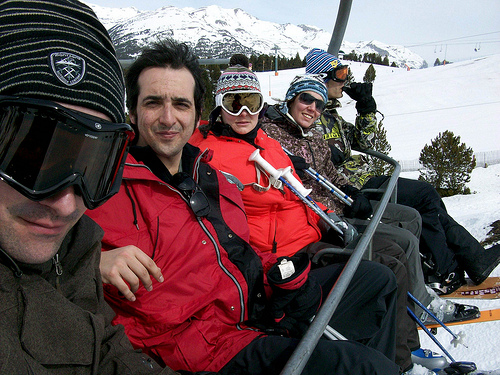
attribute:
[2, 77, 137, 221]
goggle — orange, black, here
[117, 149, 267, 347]
jacket — red, pink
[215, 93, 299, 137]
goggle — white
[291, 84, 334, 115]
sunglasses — black, worn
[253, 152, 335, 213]
pole — white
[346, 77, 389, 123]
glove — black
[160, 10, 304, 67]
mountain — capped, here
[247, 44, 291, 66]
lift — full, here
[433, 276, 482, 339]
ski — brown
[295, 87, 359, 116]
eyewear — black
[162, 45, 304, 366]
man — seated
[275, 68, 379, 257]
woman — seated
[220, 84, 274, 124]
eyeweare — white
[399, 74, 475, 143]
snow — white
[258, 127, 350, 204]
jacket — orange, green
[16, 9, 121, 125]
hat — tan, black, here, striped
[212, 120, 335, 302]
coat — red, dark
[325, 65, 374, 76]
goggles — white, worn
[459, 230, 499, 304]
boot — here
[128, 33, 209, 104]
hair — dark